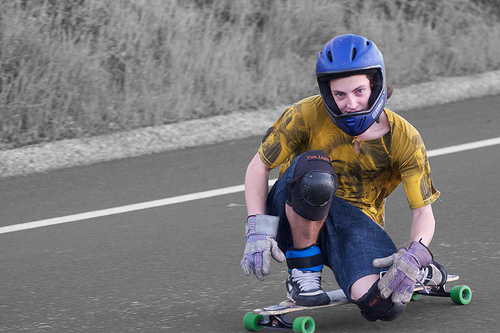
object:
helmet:
[316, 34, 390, 137]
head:
[326, 57, 380, 114]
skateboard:
[242, 271, 472, 332]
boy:
[242, 33, 446, 321]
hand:
[239, 232, 285, 280]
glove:
[239, 213, 287, 280]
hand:
[373, 252, 422, 303]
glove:
[372, 240, 432, 305]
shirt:
[258, 93, 439, 229]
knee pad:
[288, 152, 337, 221]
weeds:
[1, 1, 499, 152]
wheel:
[411, 291, 423, 300]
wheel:
[292, 316, 315, 332]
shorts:
[267, 149, 399, 306]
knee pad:
[351, 278, 408, 322]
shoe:
[284, 268, 330, 307]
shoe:
[413, 260, 447, 288]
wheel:
[241, 310, 263, 332]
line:
[0, 135, 498, 235]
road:
[2, 94, 500, 332]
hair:
[368, 70, 382, 87]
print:
[306, 155, 329, 162]